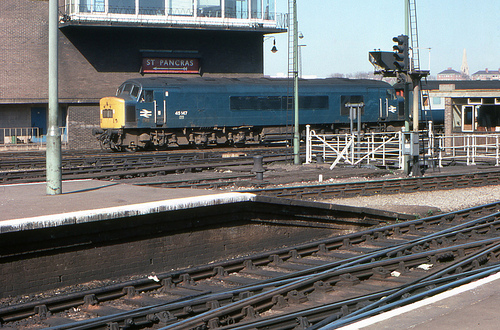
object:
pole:
[45, 0, 60, 196]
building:
[1, 2, 288, 149]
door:
[30, 108, 48, 142]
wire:
[56, 0, 291, 27]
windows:
[255, 0, 277, 21]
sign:
[140, 52, 200, 73]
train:
[100, 76, 500, 144]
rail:
[0, 139, 495, 325]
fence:
[304, 119, 499, 169]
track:
[1, 205, 497, 330]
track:
[6, 145, 413, 182]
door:
[154, 92, 166, 126]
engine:
[97, 70, 294, 149]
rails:
[303, 125, 401, 168]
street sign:
[393, 84, 404, 103]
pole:
[396, 0, 419, 176]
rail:
[6, 151, 31, 178]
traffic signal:
[394, 89, 406, 100]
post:
[44, 0, 61, 193]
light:
[392, 35, 407, 72]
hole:
[0, 191, 403, 309]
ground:
[2, 135, 497, 326]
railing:
[2, 125, 44, 147]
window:
[230, 95, 243, 111]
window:
[247, 97, 260, 110]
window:
[268, 95, 280, 110]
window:
[302, 95, 313, 110]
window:
[311, 95, 329, 110]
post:
[407, 68, 426, 177]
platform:
[345, 267, 497, 328]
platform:
[0, 179, 247, 227]